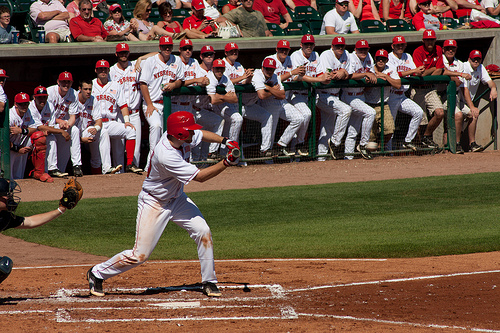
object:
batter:
[84, 108, 246, 297]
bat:
[229, 147, 242, 158]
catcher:
[0, 174, 86, 281]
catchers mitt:
[58, 175, 95, 212]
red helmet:
[167, 108, 205, 136]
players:
[4, 28, 498, 129]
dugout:
[1, 32, 500, 184]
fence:
[163, 76, 461, 167]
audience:
[0, 0, 498, 45]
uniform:
[90, 129, 219, 293]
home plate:
[50, 281, 297, 326]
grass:
[215, 182, 499, 256]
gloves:
[220, 136, 242, 167]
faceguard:
[6, 179, 23, 214]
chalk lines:
[295, 304, 500, 333]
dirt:
[19, 258, 500, 332]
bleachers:
[270, 1, 328, 33]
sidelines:
[3, 3, 500, 154]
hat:
[299, 32, 321, 45]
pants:
[87, 190, 221, 285]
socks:
[123, 138, 133, 168]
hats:
[157, 34, 176, 46]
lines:
[282, 270, 497, 295]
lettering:
[95, 94, 118, 103]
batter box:
[54, 284, 290, 302]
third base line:
[299, 261, 499, 294]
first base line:
[309, 309, 499, 332]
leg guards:
[1, 249, 14, 284]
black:
[0, 210, 21, 233]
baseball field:
[0, 171, 498, 328]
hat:
[1, 179, 8, 191]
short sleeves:
[178, 132, 201, 191]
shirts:
[159, 56, 220, 95]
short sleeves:
[141, 62, 190, 82]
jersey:
[138, 133, 205, 199]